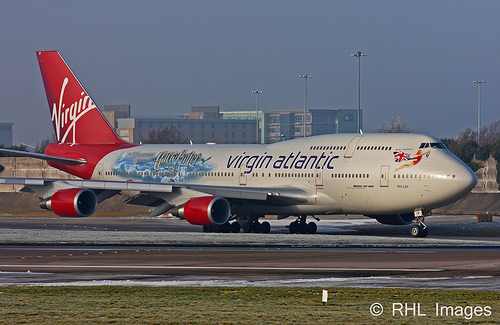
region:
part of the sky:
[213, 22, 256, 53]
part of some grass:
[236, 280, 283, 322]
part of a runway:
[198, 252, 238, 279]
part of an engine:
[200, 200, 225, 225]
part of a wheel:
[402, 212, 436, 245]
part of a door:
[370, 156, 395, 194]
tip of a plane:
[464, 176, 487, 216]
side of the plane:
[261, 141, 329, 173]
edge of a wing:
[128, 177, 170, 196]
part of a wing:
[106, 180, 143, 192]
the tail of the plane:
[0, 48, 131, 174]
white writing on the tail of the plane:
[42, 76, 104, 143]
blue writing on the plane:
[222, 149, 351, 176]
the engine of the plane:
[166, 189, 242, 228]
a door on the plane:
[343, 130, 364, 157]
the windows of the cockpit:
[416, 139, 448, 154]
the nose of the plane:
[454, 163, 487, 196]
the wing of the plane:
[0, 174, 317, 201]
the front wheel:
[404, 219, 432, 241]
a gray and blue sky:
[1, 0, 498, 150]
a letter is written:
[220, 146, 237, 168]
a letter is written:
[232, 149, 242, 171]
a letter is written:
[236, 151, 250, 170]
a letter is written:
[244, 151, 259, 177]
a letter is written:
[257, 151, 262, 170]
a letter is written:
[259, 150, 269, 172]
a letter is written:
[273, 149, 285, 172]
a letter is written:
[281, 145, 294, 167]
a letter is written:
[295, 154, 309, 167]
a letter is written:
[47, 75, 66, 142]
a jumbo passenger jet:
[0, 51, 472, 234]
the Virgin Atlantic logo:
[220, 141, 345, 176]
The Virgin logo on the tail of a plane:
[45, 83, 111, 143]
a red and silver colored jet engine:
[167, 193, 233, 223]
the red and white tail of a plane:
[30, 40, 118, 182]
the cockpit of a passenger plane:
[417, 136, 474, 212]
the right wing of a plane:
[0, 174, 304, 201]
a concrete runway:
[5, 214, 499, 286]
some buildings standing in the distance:
[100, 107, 364, 143]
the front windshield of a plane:
[415, 141, 452, 157]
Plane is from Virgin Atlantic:
[0, 39, 480, 249]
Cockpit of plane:
[410, 121, 459, 172]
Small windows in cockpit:
[420, 136, 450, 152]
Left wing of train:
[0, 163, 305, 203]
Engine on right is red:
[162, 189, 234, 232]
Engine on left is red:
[30, 180, 100, 221]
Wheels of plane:
[221, 213, 325, 238]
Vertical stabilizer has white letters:
[22, 40, 131, 145]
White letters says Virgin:
[26, 43, 124, 145]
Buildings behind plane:
[114, 97, 387, 165]